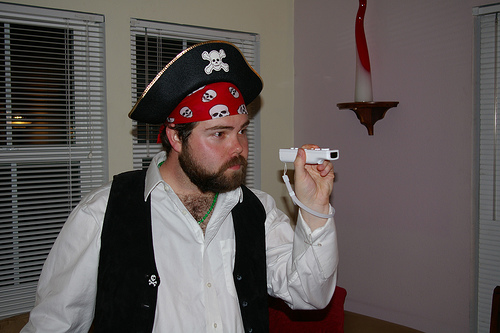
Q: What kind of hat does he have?
A: Pirate.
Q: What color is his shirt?
A: White.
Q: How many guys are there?
A: One.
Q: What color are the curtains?
A: White.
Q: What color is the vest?
A: Black.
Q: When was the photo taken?
A: At night.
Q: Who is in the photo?
A: A man.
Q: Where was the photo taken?
A: In a house.